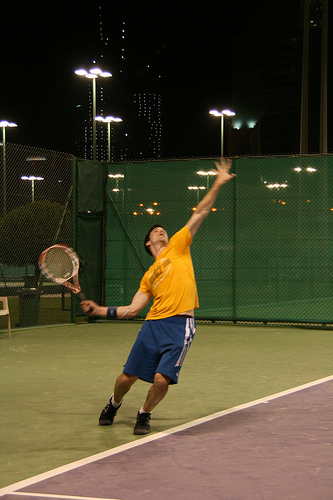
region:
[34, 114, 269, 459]
A man playing tennis.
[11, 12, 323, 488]
Tennis game being played at night.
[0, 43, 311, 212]
Lights in the background.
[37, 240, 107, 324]
Tennis racquet in man's right hand.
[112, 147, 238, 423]
Man's left arm stretched up in the air.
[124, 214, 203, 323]
Man wearing a yellow shirt.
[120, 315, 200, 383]
A pair of blue shorts.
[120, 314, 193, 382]
White stripes on blue shorts.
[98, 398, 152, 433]
A pair of black tennis shoes.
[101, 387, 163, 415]
A pair of white socks.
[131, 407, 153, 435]
A black tennis shoe.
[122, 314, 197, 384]
A blue pair of shorts.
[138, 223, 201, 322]
A yellow colored tshirt.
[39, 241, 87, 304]
A red and white tennis racquet.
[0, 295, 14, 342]
A white plastic chair.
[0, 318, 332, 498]
A brown and green tennis court.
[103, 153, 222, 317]
Green tennis court fence.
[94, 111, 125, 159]
A bright court light.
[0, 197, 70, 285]
A small rounded tree.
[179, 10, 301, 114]
the black night sky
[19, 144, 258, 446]
the man on the court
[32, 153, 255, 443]
the man holding the racquet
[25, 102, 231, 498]
the man playing tennis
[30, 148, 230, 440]
the man is serving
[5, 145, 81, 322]
the fence behind man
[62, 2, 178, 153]
the sky scraper against the night sky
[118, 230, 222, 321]
the yellow shirt on the man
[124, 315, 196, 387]
the blue shorts on the man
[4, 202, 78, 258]
the green bush behind the fence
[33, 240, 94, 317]
racket is pink and black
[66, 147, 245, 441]
tennis player wears yellow shirt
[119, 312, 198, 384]
a blue short with white stripes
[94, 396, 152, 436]
a pair of blacks shoes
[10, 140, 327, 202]
lights on the ceiling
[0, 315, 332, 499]
tennis court is green and purple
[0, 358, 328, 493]
white line on tennis court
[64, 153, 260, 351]
left arm of tennis player is up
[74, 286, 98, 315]
handle of racket is black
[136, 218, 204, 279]
hair of man is black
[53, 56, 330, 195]
lights on a tennis court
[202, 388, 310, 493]
purple ground on a tennis court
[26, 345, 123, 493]
a green tennis court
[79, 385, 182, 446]
black athletic sneakers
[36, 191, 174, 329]
a man holding a tennis racket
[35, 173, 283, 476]
a man playing tennis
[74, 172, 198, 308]
a man wearing a yellow shirt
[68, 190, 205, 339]
a man wearing a armband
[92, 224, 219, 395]
a man wearing blue shorts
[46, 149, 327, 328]
a green fence on a tennis court